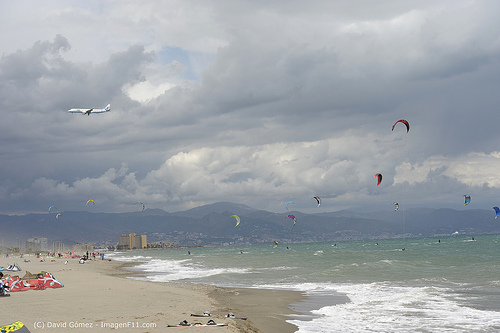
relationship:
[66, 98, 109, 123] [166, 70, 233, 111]
plane in sky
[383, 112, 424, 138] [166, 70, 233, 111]
kite in sky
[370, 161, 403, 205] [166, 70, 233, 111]
kite in sky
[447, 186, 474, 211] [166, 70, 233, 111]
kite in sky